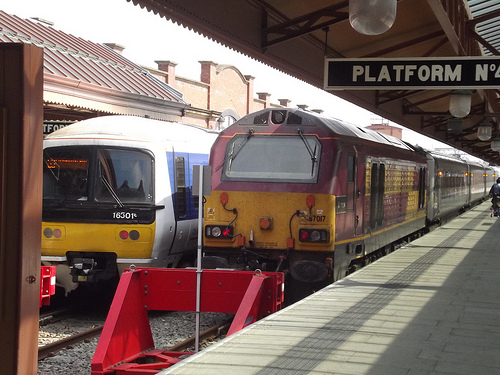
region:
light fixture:
[250, 1, 425, 59]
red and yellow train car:
[202, 109, 442, 254]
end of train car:
[42, 119, 196, 282]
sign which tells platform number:
[318, 50, 498, 87]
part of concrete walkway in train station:
[311, 269, 497, 367]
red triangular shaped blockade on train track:
[102, 263, 287, 373]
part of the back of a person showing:
[485, 174, 499, 216]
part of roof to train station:
[7, 34, 246, 128]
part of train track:
[35, 306, 98, 354]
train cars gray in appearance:
[431, 156, 491, 217]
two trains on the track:
[37, 56, 496, 334]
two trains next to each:
[42, 32, 472, 354]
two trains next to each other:
[52, 42, 483, 312]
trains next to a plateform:
[47, 50, 487, 372]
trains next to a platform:
[62, 62, 462, 362]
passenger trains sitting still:
[46, 34, 496, 362]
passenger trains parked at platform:
[47, 25, 497, 299]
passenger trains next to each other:
[41, 50, 460, 316]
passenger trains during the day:
[51, 49, 469, 326]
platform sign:
[309, 14, 498, 149]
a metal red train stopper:
[92, 268, 259, 360]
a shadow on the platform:
[346, 274, 491, 304]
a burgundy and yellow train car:
[203, 105, 394, 260]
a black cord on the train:
[219, 206, 242, 218]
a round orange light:
[257, 214, 282, 231]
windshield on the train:
[231, 130, 322, 164]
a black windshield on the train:
[294, 129, 320, 164]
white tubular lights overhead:
[435, 87, 494, 143]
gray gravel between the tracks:
[54, 353, 83, 373]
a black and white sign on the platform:
[323, 43, 487, 109]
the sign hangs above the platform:
[327, 58, 497, 93]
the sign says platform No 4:
[324, 60, 499, 91]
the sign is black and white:
[328, 59, 499, 89]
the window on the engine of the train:
[227, 134, 324, 185]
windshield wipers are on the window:
[217, 131, 258, 180]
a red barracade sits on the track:
[87, 261, 287, 373]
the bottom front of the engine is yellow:
[208, 188, 343, 257]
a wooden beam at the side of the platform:
[4, 43, 52, 373]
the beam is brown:
[2, 45, 44, 374]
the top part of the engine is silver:
[208, 108, 336, 199]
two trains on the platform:
[25, 45, 497, 327]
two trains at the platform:
[25, 2, 458, 372]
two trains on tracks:
[11, 10, 479, 366]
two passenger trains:
[21, 28, 436, 324]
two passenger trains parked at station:
[51, 41, 473, 339]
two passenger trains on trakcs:
[36, 68, 432, 359]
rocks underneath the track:
[22, 306, 114, 373]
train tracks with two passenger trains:
[24, 88, 424, 373]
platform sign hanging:
[297, 4, 499, 149]